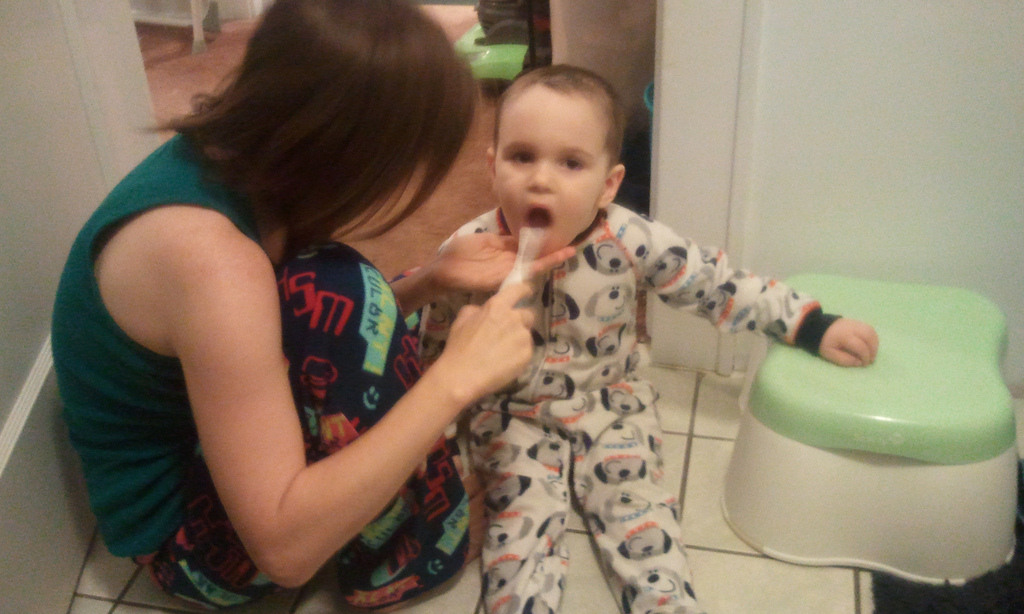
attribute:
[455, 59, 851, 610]
boy — little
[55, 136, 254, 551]
shirt — green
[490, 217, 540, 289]
toothbrush — white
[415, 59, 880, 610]
baby — young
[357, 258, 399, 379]
patch — green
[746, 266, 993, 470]
seat cover — green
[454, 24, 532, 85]
paper — green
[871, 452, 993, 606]
carpet — black